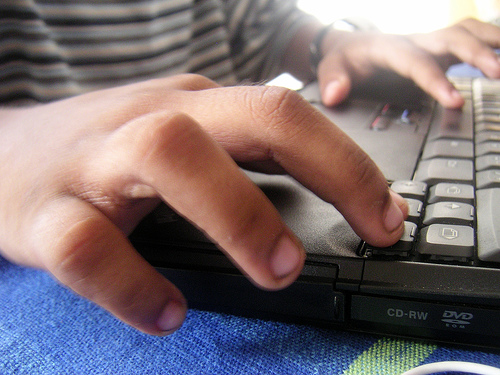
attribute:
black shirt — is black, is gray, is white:
[13, 7, 412, 110]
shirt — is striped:
[1, 0, 316, 109]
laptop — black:
[122, 64, 498, 332]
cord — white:
[398, 357, 491, 373]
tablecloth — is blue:
[2, 261, 493, 373]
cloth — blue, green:
[20, 295, 379, 368]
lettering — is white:
[384, 291, 499, 341]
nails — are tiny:
[261, 234, 301, 274]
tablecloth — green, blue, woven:
[1, 275, 121, 373]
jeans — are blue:
[46, 307, 142, 374]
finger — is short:
[35, 193, 191, 338]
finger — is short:
[104, 110, 309, 291]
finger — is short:
[193, 84, 407, 242]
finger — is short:
[363, 35, 461, 115]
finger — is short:
[428, 26, 499, 83]